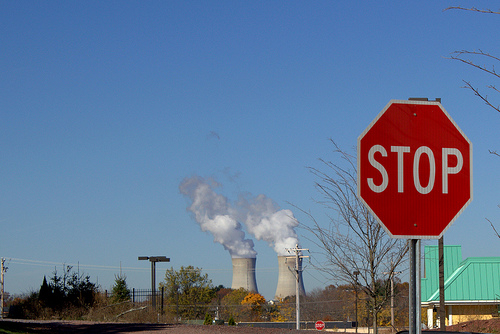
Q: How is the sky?
A: Cloudless.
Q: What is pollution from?
A: Smoke stacks.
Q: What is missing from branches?
A: Leaves.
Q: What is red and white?
A: Stop sign.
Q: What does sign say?
A: Stop.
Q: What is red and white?
A: Sign.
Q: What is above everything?
A: The sky.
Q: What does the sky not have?
A: Clouds.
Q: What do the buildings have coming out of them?
A: Steam.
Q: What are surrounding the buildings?
A: Trees.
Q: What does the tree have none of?
A: Branches.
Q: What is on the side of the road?
A: A red sign.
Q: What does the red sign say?
A: STOP.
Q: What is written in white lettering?
A: STOP.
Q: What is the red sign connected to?
A: A silver pole.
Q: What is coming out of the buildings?
A: Smoke.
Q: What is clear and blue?
A: The sky.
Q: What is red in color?
A: The sign.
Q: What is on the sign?
A: Writing.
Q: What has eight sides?
A: Sign.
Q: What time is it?
A: Afternoon.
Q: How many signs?
A: 1.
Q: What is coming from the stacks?
A: Smoke.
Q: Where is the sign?
A: On the pole.